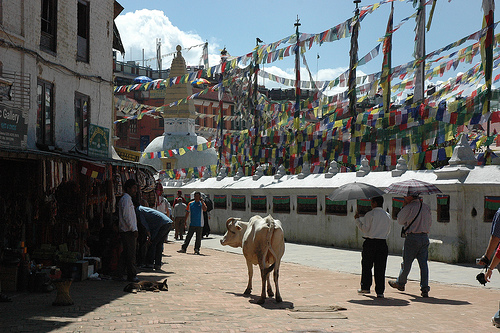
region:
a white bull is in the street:
[226, 213, 298, 290]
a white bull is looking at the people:
[214, 213, 308, 303]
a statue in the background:
[143, 45, 224, 160]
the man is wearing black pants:
[358, 235, 391, 297]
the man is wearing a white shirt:
[359, 210, 389, 235]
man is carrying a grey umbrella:
[335, 180, 373, 206]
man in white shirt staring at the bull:
[116, 193, 141, 226]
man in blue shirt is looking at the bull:
[183, 200, 211, 225]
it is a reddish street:
[184, 260, 230, 320]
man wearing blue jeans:
[401, 234, 428, 283]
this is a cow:
[213, 206, 290, 301]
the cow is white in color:
[218, 200, 287, 302]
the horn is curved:
[224, 215, 234, 231]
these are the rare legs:
[253, 264, 283, 301]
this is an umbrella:
[338, 178, 371, 198]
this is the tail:
[262, 247, 279, 272]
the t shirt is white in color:
[364, 210, 387, 233]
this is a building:
[10, 9, 113, 142]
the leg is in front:
[388, 263, 410, 294]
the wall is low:
[311, 217, 331, 241]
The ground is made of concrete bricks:
[112, 305, 315, 331]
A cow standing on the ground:
[216, 198, 298, 304]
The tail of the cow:
[259, 218, 279, 282]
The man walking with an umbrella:
[328, 160, 394, 302]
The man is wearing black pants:
[354, 236, 394, 299]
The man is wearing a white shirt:
[356, 205, 396, 245]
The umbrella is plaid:
[387, 173, 444, 201]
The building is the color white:
[263, 176, 348, 243]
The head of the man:
[118, 171, 143, 198]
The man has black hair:
[119, 173, 146, 198]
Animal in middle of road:
[201, 207, 301, 312]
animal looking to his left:
[215, 210, 285, 307]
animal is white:
[214, 214, 285, 304]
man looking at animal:
[109, 168, 139, 293]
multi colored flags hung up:
[212, 102, 499, 160]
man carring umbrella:
[325, 168, 396, 306]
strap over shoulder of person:
[406, 203, 436, 238]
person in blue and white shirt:
[183, 181, 203, 268]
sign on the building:
[71, 119, 112, 177]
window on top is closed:
[26, 75, 62, 160]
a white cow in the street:
[218, 215, 288, 310]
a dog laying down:
[123, 276, 172, 296]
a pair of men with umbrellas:
[331, 177, 444, 302]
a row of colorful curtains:
[205, 191, 368, 222]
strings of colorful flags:
[208, 44, 496, 171]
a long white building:
[160, 161, 477, 260]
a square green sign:
[84, 119, 116, 161]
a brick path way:
[69, 238, 389, 323]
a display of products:
[37, 160, 162, 201]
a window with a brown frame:
[33, 73, 60, 154]